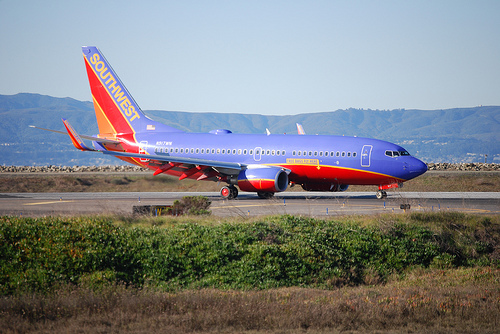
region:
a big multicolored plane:
[48, 31, 457, 210]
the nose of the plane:
[417, 153, 436, 180]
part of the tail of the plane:
[43, 108, 134, 171]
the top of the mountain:
[2, 88, 64, 108]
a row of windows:
[139, 123, 364, 173]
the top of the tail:
[58, 39, 149, 130]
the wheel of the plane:
[210, 178, 241, 203]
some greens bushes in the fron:
[11, 209, 472, 286]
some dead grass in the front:
[61, 290, 460, 322]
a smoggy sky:
[153, 18, 445, 87]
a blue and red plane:
[83, 41, 441, 185]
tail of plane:
[87, 40, 142, 135]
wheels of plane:
[213, 187, 239, 197]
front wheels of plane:
[370, 186, 390, 197]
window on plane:
[378, 145, 411, 161]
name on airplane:
[83, 47, 129, 127]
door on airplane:
[251, 143, 263, 163]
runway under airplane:
[70, 190, 455, 201]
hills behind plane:
[250, 80, 495, 126]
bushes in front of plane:
[99, 210, 471, 292]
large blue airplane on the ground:
[65, 39, 430, 207]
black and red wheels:
[214, 180, 240, 202]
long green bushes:
[19, 210, 499, 295]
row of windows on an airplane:
[148, 138, 361, 161]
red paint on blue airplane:
[262, 155, 401, 187]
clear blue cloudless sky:
[160, 12, 495, 87]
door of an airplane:
[357, 140, 379, 171]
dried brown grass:
[72, 289, 443, 332]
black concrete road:
[12, 190, 498, 217]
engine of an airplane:
[219, 155, 294, 196]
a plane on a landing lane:
[53, 34, 444, 211]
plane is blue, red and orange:
[55, 33, 435, 194]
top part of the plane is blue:
[137, 120, 424, 165]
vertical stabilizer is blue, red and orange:
[70, 41, 152, 132]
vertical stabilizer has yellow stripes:
[71, 41, 151, 136]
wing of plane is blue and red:
[50, 107, 245, 172]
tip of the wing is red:
[51, 110, 91, 155]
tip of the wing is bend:
[48, 111, 93, 156]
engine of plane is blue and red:
[234, 162, 294, 197]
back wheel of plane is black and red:
[216, 179, 241, 201]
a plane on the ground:
[59, 11, 489, 208]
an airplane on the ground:
[40, 26, 446, 267]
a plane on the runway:
[33, 13, 461, 248]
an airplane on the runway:
[29, 26, 469, 254]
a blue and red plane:
[55, 28, 435, 224]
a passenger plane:
[34, 28, 455, 239]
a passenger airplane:
[43, 45, 480, 260]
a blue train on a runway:
[33, 30, 439, 250]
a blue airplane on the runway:
[52, 27, 457, 257]